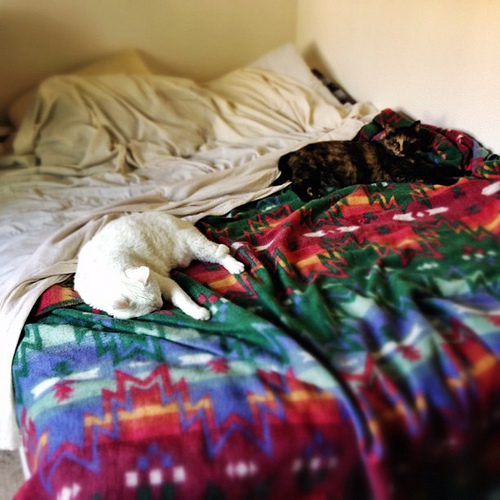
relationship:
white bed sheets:
[2, 166, 282, 235] [2, 73, 270, 211]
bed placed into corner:
[2, 3, 499, 497] [4, 2, 489, 451]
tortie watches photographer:
[269, 116, 477, 206] [274, 119, 473, 203]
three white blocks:
[120, 465, 187, 488] [124, 465, 189, 488]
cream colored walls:
[2, 2, 498, 88] [4, 1, 496, 95]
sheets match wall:
[2, 73, 270, 211] [4, 16, 279, 164]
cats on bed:
[73, 115, 476, 325] [69, 116, 476, 326]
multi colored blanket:
[247, 201, 498, 429] [252, 199, 500, 495]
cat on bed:
[269, 116, 477, 206] [269, 116, 477, 206]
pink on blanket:
[344, 208, 399, 246] [349, 206, 401, 247]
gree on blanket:
[339, 256, 500, 293] [327, 261, 427, 307]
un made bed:
[5, 41, 369, 223] [0, 45, 288, 242]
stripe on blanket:
[97, 360, 192, 412] [90, 337, 169, 368]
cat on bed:
[71, 207, 247, 332] [71, 207, 247, 332]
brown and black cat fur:
[274, 119, 473, 203] [269, 116, 477, 206]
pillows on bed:
[0, 38, 349, 135] [0, 38, 349, 135]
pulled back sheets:
[6, 111, 364, 288] [0, 69, 386, 459]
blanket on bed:
[208, 204, 495, 499] [31, 102, 480, 459]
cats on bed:
[73, 115, 476, 325] [27, 61, 473, 473]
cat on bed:
[269, 116, 477, 206] [27, 61, 473, 473]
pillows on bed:
[0, 38, 349, 135] [27, 61, 473, 473]